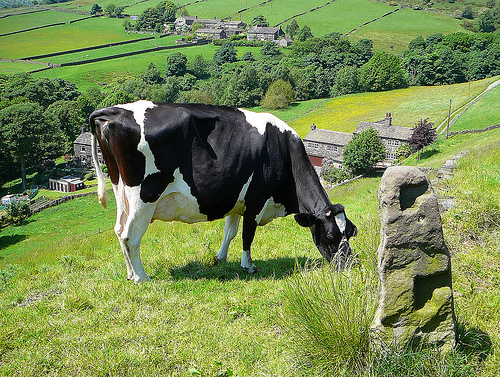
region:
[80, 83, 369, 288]
a cow on the hill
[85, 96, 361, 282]
a cow eating grass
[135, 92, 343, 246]
the body is mostly black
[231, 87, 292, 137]
a white spot on top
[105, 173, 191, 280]
his legs are white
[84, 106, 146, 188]
a brown spot on the back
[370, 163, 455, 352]
a rock pillar on the grass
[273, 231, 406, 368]
a large tuft of grass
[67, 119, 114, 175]
a building at the bottom of the hill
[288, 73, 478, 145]
yellow flowers in the field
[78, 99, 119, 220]
black and white cow tail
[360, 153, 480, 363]
Grey rock in a grassy field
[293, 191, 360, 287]
Cow eating green grass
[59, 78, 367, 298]
Cow standing on top of a hill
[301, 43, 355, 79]
Green trees at the bottom of a hill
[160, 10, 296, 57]
A group of houses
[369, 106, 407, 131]
A chimney of a house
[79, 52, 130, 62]
A fence in a green field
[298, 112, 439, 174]
Two houses at the bottom of a hill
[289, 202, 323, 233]
The right ear of a black and white cow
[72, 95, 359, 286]
a black and white cow eating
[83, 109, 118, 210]
a tail of a cow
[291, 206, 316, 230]
an ear of a cow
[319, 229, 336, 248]
the eye of a cow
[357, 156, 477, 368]
a rock marker in a field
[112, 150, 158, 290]
the hind leg of a cow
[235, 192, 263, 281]
the front leg of a cow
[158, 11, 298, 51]
a group of buildings in the distance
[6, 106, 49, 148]
the leaves of a tree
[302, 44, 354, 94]
the leaves of several trees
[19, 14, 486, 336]
a cow in the country side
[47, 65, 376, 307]
the cow is black and white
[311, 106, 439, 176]
structures in the background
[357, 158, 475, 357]
a stone marker on the ground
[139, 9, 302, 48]
a small village in the background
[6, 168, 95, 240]
parts of a farming community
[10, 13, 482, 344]
this area has rolling hills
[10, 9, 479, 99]
fields in the environment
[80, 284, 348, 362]
green grass all around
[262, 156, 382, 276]
the cow is grazing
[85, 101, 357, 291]
a cow standing in a field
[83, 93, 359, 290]
a black and white cow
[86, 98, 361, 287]
a multi-colored cow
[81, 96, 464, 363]
a cow standing beside a rock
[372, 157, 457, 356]
a rock on the ground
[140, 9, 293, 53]
houses in the distance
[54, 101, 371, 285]
a cow standing on a hill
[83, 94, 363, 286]
a cow grazing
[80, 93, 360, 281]
a black and white mammal